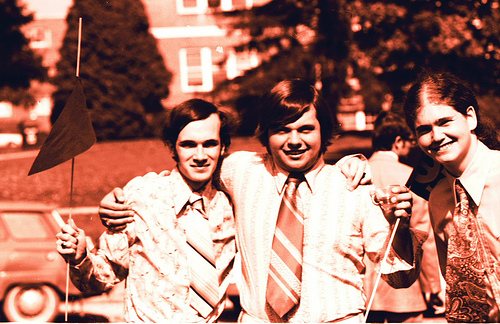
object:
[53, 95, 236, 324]
man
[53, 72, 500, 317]
friends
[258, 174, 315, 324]
ties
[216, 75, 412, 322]
man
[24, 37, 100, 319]
flag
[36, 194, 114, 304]
end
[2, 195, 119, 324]
wagon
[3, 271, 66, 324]
tire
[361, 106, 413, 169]
person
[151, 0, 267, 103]
building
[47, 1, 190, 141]
trees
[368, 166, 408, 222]
cup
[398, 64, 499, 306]
man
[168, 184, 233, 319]
tie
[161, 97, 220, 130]
hair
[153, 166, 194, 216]
collar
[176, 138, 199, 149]
eyes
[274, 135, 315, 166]
smile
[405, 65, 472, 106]
hairdo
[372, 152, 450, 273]
black flag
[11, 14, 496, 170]
background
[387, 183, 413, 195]
ring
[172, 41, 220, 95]
window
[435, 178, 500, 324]
tie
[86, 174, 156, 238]
arm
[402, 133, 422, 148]
glasses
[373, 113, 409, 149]
hair